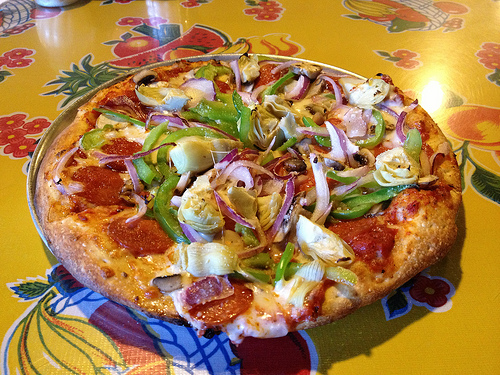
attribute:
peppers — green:
[90, 65, 427, 280]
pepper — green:
[152, 177, 183, 241]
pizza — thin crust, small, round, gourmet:
[30, 46, 465, 345]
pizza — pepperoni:
[21, 38, 482, 365]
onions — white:
[204, 139, 326, 245]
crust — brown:
[341, 126, 447, 306]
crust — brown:
[400, 101, 460, 284]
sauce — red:
[345, 218, 390, 258]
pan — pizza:
[18, 50, 368, 262]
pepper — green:
[277, 235, 299, 285]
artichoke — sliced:
[151, 172, 186, 240]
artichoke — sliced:
[329, 182, 409, 217]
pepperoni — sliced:
[72, 164, 124, 209]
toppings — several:
[95, 79, 410, 293]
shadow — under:
[303, 330, 380, 354]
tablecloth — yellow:
[0, 1, 495, 372]